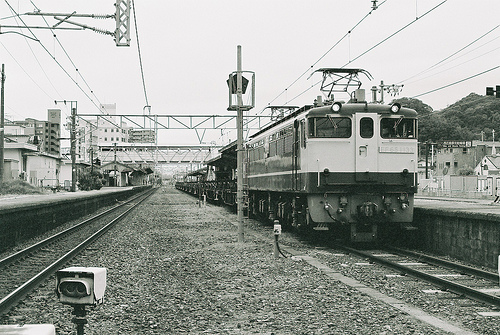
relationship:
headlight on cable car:
[332, 101, 344, 112] [195, 99, 423, 248]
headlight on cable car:
[392, 102, 401, 113] [195, 99, 423, 248]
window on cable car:
[381, 117, 416, 140] [195, 99, 423, 248]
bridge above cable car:
[73, 114, 286, 165] [195, 99, 423, 248]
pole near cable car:
[235, 43, 245, 241] [195, 99, 423, 248]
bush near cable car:
[77, 171, 108, 192] [195, 99, 423, 248]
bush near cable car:
[1, 179, 41, 195] [195, 99, 423, 248]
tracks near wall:
[0, 187, 163, 317] [0, 184, 153, 253]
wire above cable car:
[267, 11, 367, 106] [195, 99, 423, 248]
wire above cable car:
[131, 0, 148, 106] [195, 99, 423, 248]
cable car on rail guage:
[195, 99, 423, 248] [330, 240, 500, 304]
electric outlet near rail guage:
[273, 219, 289, 259] [330, 240, 500, 304]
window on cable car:
[308, 116, 354, 139] [195, 99, 423, 248]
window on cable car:
[360, 117, 376, 139] [195, 99, 423, 248]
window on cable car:
[269, 142, 277, 157] [195, 99, 423, 248]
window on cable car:
[253, 148, 260, 161] [195, 99, 423, 248]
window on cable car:
[254, 146, 260, 161] [195, 99, 423, 248]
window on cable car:
[258, 146, 267, 161] [195, 99, 423, 248]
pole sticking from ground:
[272, 220, 284, 259] [99, 207, 353, 324]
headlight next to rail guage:
[332, 104, 340, 111] [330, 240, 500, 304]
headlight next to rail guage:
[391, 105, 399, 112] [330, 240, 500, 304]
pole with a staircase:
[227, 111, 254, 248] [234, 118, 248, 237]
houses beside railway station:
[1, 90, 126, 210] [44, 84, 435, 327]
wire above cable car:
[250, 0, 449, 127] [195, 99, 423, 248]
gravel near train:
[131, 219, 251, 301] [234, 76, 475, 300]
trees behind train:
[402, 90, 499, 148] [161, 94, 426, 246]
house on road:
[471, 152, 498, 201] [414, 181, 499, 221]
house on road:
[469, 154, 500, 191] [414, 181, 499, 221]